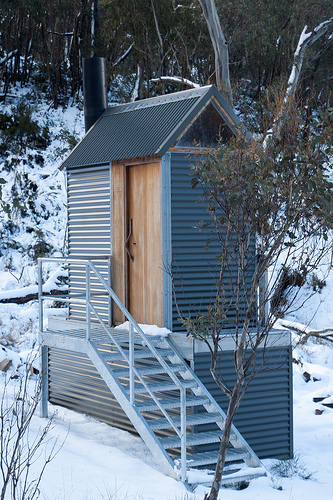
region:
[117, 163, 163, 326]
A wooden door.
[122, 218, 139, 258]
The handle for the door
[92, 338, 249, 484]
The stairs to the patio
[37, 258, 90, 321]
A gurad rail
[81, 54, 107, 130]
A vent for the room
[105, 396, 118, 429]
Rivets in the wall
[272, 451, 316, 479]
Grass in the snow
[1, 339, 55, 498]
Bare bushes on the ground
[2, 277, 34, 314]
Log on the snowy ground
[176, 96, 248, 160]
Window on the roof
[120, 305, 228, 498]
a flight of stairs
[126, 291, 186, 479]
a flight of stairs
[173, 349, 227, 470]
a flight of stairs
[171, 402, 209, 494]
a flight of stairs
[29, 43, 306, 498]
primarily steel+slate blue snow cabin-perhaps even tiny house-with snow on it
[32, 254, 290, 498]
cold metal steps+cold metal handrails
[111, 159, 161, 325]
an inset wooden door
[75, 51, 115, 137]
a black chimney possibly made from plastic piping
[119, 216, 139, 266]
an unusually curve-warped door handle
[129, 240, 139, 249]
lock beside+beneath door handle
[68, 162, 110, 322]
silvertone aluminium siding beside door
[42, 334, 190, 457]
silvertone aluminium siding beneath door, @ what looks like structure's basement, maybe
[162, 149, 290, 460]
i believe to the right is also aluminium siding, but painted a very sophisticated dark steel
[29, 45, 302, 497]
structure is primarily vertical, & clearly uses space efficiently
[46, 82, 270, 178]
the roof is black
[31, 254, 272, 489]
the stairs are grey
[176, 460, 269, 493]
the snow is white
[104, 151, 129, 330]
the door is glass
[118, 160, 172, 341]
the door is brown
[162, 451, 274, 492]
the snow is on the stairs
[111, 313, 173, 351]
the snow is in front of the door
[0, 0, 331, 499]
the trees are barren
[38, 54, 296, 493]
the building is small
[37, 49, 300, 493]
the building has now windows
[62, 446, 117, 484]
Ground is white color.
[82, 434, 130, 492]
Snow is in ground.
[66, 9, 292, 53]
Woods are brown color.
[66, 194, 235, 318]
House is blue color.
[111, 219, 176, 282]
Door is brown color.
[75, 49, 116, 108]
Chimney is black color.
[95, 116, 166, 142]
Roof is grey color.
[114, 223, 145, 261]
Handle is brown color.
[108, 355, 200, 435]
Steps are grey color.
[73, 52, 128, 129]
Chimney is besides the roof.